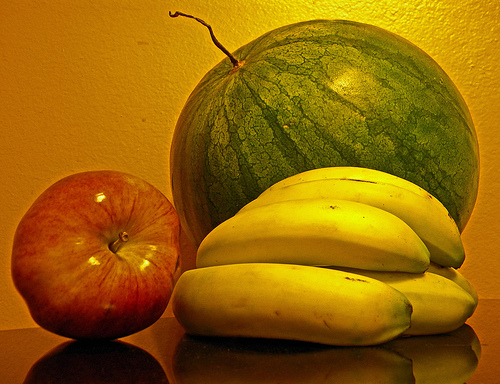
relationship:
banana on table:
[171, 244, 420, 360] [1, 307, 495, 374]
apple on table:
[6, 164, 188, 345] [1, 307, 495, 374]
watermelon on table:
[160, 10, 484, 223] [1, 307, 495, 374]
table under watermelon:
[1, 307, 495, 374] [160, 10, 484, 223]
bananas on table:
[174, 164, 481, 347] [1, 307, 495, 374]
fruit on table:
[12, 3, 488, 349] [1, 307, 495, 374]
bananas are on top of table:
[174, 164, 481, 347] [1, 307, 495, 374]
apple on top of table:
[6, 164, 188, 345] [1, 307, 495, 374]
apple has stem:
[6, 164, 188, 345] [100, 221, 136, 257]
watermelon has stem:
[160, 10, 484, 223] [168, 9, 255, 74]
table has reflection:
[1, 307, 495, 374] [24, 332, 172, 383]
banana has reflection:
[171, 244, 420, 360] [273, 327, 486, 383]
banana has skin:
[171, 244, 420, 360] [299, 285, 387, 316]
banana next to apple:
[171, 244, 420, 360] [6, 164, 188, 345]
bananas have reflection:
[174, 164, 481, 347] [273, 327, 486, 383]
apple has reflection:
[6, 164, 188, 345] [24, 332, 172, 383]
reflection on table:
[24, 332, 172, 383] [1, 307, 495, 374]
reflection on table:
[273, 327, 486, 383] [1, 307, 495, 374]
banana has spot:
[171, 244, 420, 360] [336, 273, 374, 287]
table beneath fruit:
[1, 307, 495, 374] [12, 3, 488, 349]